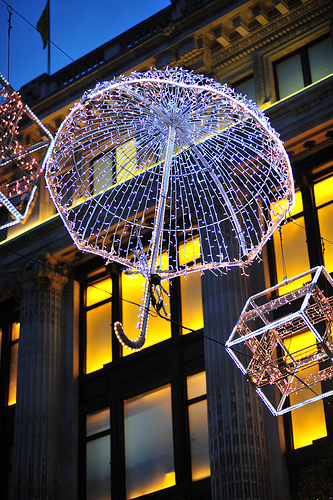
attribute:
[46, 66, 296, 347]
umbrella — lit, metal, aluminum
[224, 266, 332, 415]
box — illuminated, suspended, aluminum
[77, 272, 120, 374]
window — lit, glass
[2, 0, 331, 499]
building — illuminated, brown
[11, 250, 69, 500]
pillar — white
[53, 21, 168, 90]
light — blue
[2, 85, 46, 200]
light — red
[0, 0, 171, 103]
sky — blue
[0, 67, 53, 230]
structure — aluminum, metal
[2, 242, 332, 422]
wire — metal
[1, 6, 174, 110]
fence — small